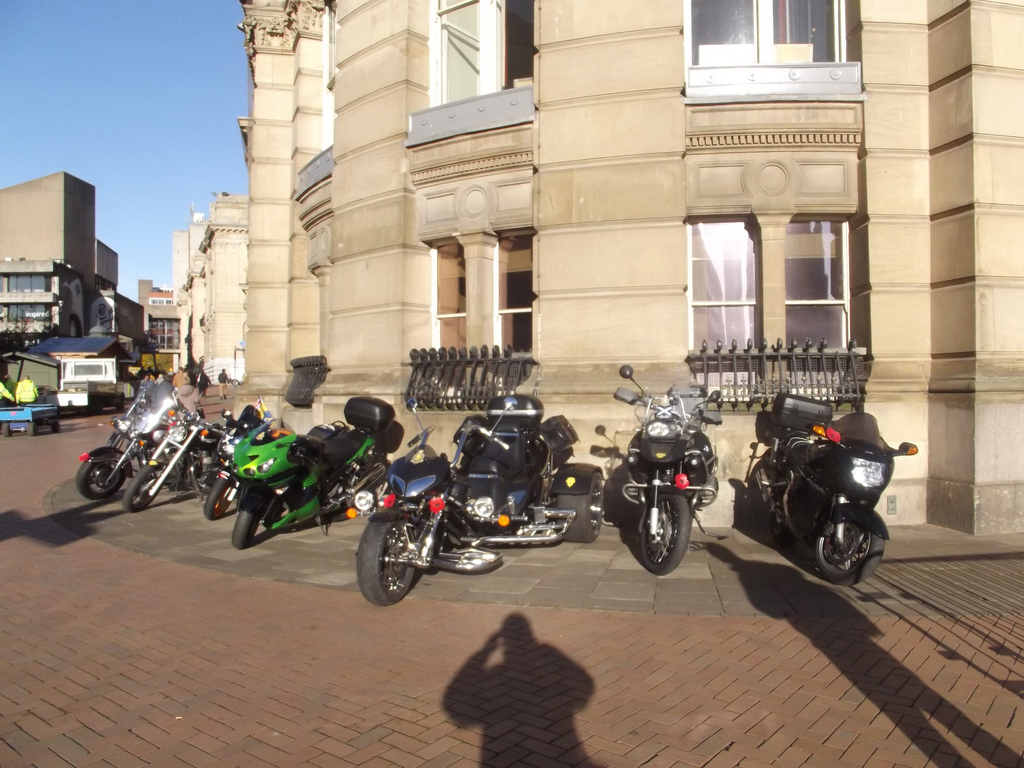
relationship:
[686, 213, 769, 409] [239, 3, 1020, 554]
window on a building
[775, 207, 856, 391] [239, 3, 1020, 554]
window on a building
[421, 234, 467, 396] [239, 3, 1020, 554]
window on a building